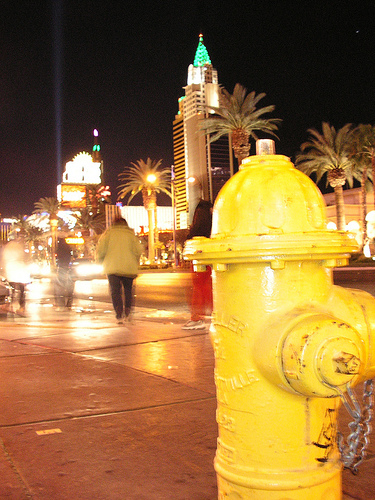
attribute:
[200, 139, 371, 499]
hydrant — yellow, metal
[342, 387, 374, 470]
chain — silver, hanging, shiny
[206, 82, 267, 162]
tree — tall, light brown, green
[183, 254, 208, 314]
pants — red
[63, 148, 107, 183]
sign — large, neon, bright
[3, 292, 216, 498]
sidewalk — cement, dry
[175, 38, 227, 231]
building — tall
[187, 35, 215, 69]
roof — blue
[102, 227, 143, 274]
jacket — tan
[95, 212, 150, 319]
woman — walking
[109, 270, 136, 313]
pants — black